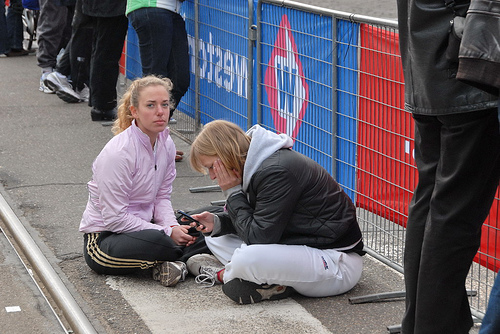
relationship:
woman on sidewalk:
[81, 74, 366, 306] [1, 65, 499, 332]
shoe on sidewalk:
[188, 254, 223, 285] [1, 65, 499, 332]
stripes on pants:
[88, 232, 163, 270] [203, 234, 364, 296]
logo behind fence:
[263, 14, 310, 140] [127, 0, 499, 332]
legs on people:
[2, 0, 190, 130] [1, 1, 198, 126]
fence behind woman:
[127, 0, 499, 332] [81, 74, 366, 306]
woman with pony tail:
[81, 74, 366, 306] [117, 79, 135, 131]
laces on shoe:
[196, 269, 216, 290] [188, 254, 223, 285]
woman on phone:
[81, 74, 366, 306] [178, 210, 206, 229]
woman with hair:
[81, 74, 366, 306] [114, 74, 175, 128]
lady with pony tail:
[78, 74, 212, 294] [117, 79, 135, 131]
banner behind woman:
[128, 2, 500, 272] [81, 74, 366, 306]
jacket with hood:
[212, 146, 367, 254] [242, 124, 295, 187]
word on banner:
[186, 31, 257, 100] [128, 2, 500, 272]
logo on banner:
[263, 14, 310, 140] [128, 2, 500, 272]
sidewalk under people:
[1, 65, 499, 332] [1, 1, 198, 126]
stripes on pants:
[88, 232, 163, 270] [83, 229, 221, 275]